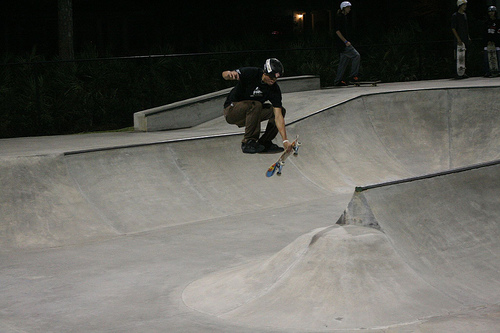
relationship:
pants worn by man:
[215, 99, 285, 143] [222, 57, 293, 155]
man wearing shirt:
[222, 57, 293, 155] [215, 60, 295, 122]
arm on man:
[216, 63, 246, 84] [218, 53, 293, 152]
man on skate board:
[222, 57, 293, 155] [262, 131, 302, 177]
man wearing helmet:
[222, 57, 293, 155] [338, 0, 350, 10]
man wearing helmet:
[222, 57, 293, 155] [262, 52, 286, 77]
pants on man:
[221, 99, 286, 147] [218, 55, 295, 165]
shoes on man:
[243, 134, 286, 155] [243, 111, 290, 160]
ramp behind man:
[328, 82, 432, 197] [226, 62, 307, 168]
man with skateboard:
[220, 57, 300, 158] [259, 135, 301, 177]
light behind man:
[294, 12, 305, 19] [222, 54, 294, 156]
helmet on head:
[262, 59, 287, 77] [260, 66, 280, 87]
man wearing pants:
[222, 57, 293, 155] [224, 98, 285, 140]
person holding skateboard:
[450, 31, 472, 80] [263, 134, 300, 177]